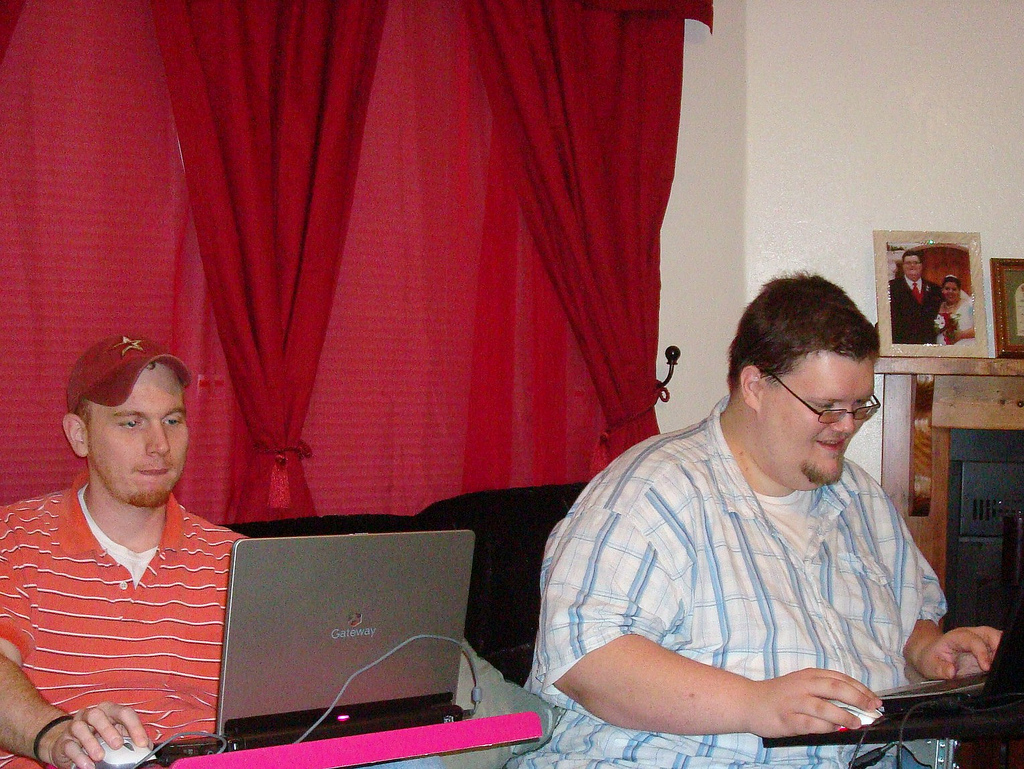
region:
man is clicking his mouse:
[11, 339, 252, 764]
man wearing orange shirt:
[6, 336, 245, 748]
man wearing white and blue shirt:
[530, 275, 995, 765]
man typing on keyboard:
[539, 276, 1007, 760]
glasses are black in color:
[748, 351, 879, 434]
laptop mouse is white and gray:
[77, 724, 166, 764]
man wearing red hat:
[52, 323, 202, 410]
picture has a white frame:
[871, 222, 999, 368]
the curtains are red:
[1, 3, 709, 526]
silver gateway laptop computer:
[150, 529, 468, 760]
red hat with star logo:
[56, 330, 208, 416]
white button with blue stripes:
[526, 387, 967, 767]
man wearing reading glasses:
[719, 248, 881, 509]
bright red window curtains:
[148, 0, 443, 525]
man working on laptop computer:
[1, 336, 324, 748]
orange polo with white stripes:
[0, 472, 323, 766]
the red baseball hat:
[58, 326, 198, 425]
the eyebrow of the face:
[112, 404, 147, 423]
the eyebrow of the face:
[156, 399, 186, 420]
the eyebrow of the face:
[807, 392, 843, 405]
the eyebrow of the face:
[854, 383, 875, 402]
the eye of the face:
[117, 415, 140, 431]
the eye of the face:
[159, 409, 183, 432]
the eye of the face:
[811, 393, 835, 412]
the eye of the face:
[849, 392, 870, 403]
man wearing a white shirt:
[584, 437, 935, 763]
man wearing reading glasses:
[771, 376, 893, 440]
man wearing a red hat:
[49, 328, 192, 427]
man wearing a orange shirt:
[6, 486, 278, 763]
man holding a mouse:
[793, 654, 893, 737]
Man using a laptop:
[834, 481, 1021, 698]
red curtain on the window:
[3, 6, 667, 675]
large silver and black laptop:
[213, 523, 483, 727]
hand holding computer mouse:
[59, 704, 168, 766]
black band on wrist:
[18, 696, 67, 758]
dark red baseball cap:
[59, 326, 189, 416]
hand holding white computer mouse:
[759, 660, 887, 743]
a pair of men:
[35, 241, 996, 761]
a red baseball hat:
[41, 297, 215, 434]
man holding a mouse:
[45, 686, 153, 766]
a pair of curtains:
[18, 10, 683, 485]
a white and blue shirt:
[532, 427, 995, 766]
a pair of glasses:
[771, 382, 901, 460]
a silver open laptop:
[181, 516, 496, 741]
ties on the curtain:
[206, 411, 339, 513]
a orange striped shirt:
[12, 496, 257, 715]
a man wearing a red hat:
[67, 316, 210, 422]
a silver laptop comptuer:
[178, 512, 486, 751]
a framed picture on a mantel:
[870, 219, 1001, 371]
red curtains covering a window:
[349, 71, 695, 460]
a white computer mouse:
[93, 716, 177, 765]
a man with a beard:
[792, 440, 851, 495]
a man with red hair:
[735, 262, 875, 377]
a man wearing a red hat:
[60, 335, 190, 425]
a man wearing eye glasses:
[760, 358, 888, 432]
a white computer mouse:
[96, 731, 155, 766]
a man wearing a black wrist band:
[23, 700, 81, 765]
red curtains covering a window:
[466, 6, 685, 456]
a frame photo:
[867, 212, 998, 364]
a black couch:
[443, 484, 637, 688]